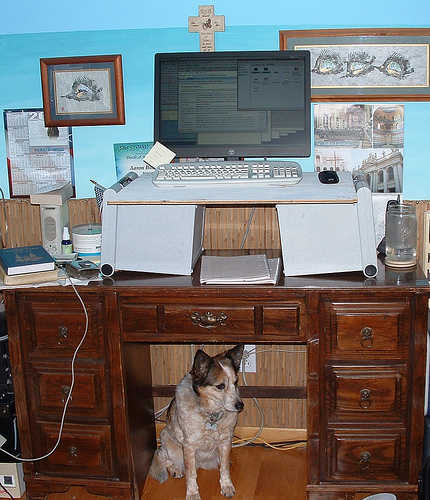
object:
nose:
[236, 401, 245, 410]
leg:
[182, 441, 200, 500]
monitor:
[158, 59, 307, 146]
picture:
[294, 44, 428, 89]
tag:
[209, 411, 219, 427]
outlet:
[238, 344, 257, 374]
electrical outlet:
[234, 345, 257, 374]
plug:
[242, 350, 249, 360]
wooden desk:
[99, 170, 380, 279]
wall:
[5, 4, 428, 242]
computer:
[151, 49, 311, 187]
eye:
[214, 383, 225, 391]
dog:
[149, 342, 246, 500]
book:
[0, 245, 56, 276]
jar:
[385, 203, 417, 261]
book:
[0, 264, 60, 285]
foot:
[184, 492, 201, 498]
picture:
[52, 70, 112, 116]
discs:
[73, 223, 102, 235]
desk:
[2, 249, 430, 500]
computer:
[0, 335, 20, 461]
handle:
[360, 327, 374, 348]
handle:
[357, 388, 374, 410]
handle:
[358, 451, 373, 472]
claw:
[220, 482, 235, 499]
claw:
[184, 483, 203, 499]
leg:
[218, 424, 236, 498]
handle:
[191, 311, 228, 329]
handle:
[56, 326, 69, 345]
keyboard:
[152, 160, 304, 188]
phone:
[318, 170, 340, 184]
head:
[190, 344, 246, 416]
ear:
[192, 349, 212, 383]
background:
[144, 345, 312, 451]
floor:
[1, 436, 310, 497]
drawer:
[123, 305, 300, 340]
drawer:
[324, 364, 411, 422]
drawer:
[325, 433, 408, 483]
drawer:
[33, 309, 96, 351]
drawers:
[333, 309, 402, 358]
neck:
[184, 376, 235, 429]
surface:
[7, 248, 430, 288]